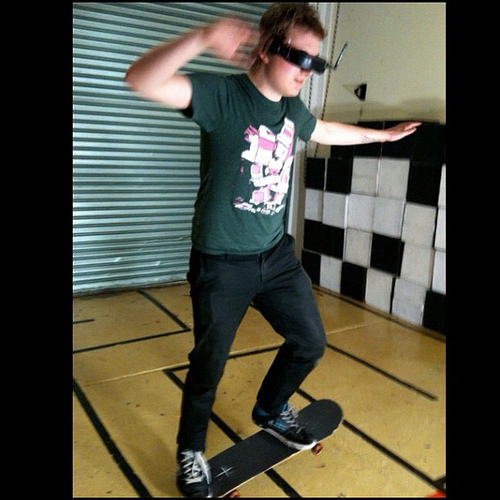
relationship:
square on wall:
[301, 188, 346, 228] [303, 148, 455, 316]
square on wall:
[316, 190, 349, 227] [293, 25, 443, 331]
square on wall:
[349, 157, 384, 198] [277, 13, 445, 333]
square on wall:
[370, 159, 410, 204] [277, 13, 445, 333]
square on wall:
[347, 191, 378, 235] [293, 25, 443, 331]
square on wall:
[369, 195, 407, 238] [296, 41, 448, 339]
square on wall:
[341, 229, 374, 264] [293, 25, 443, 331]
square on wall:
[315, 255, 345, 291] [296, 41, 448, 339]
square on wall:
[361, 269, 394, 317] [293, 25, 443, 331]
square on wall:
[391, 279, 426, 329] [303, 18, 445, 317]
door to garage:
[75, 4, 296, 302] [81, 6, 442, 480]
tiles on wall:
[298, 121, 445, 311] [277, 13, 445, 333]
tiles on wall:
[298, 121, 445, 326] [303, 18, 445, 317]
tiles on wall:
[298, 121, 445, 326] [290, 8, 442, 342]